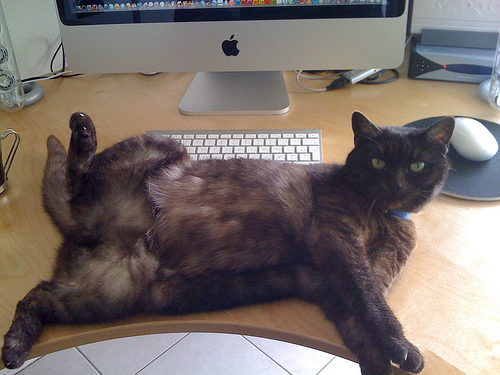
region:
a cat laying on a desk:
[4, 93, 480, 373]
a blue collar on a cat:
[333, 167, 418, 225]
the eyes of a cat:
[367, 155, 434, 172]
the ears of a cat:
[347, 109, 457, 148]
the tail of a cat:
[39, 130, 80, 231]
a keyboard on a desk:
[146, 122, 337, 169]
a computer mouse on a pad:
[447, 111, 499, 167]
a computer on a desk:
[50, 3, 432, 110]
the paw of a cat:
[60, 110, 102, 151]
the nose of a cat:
[383, 172, 405, 194]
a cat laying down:
[34, 93, 472, 331]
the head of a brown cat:
[345, 108, 446, 215]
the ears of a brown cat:
[325, 99, 466, 146]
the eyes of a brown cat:
[351, 141, 439, 181]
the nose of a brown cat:
[390, 168, 415, 193]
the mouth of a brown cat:
[380, 186, 412, 213]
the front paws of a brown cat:
[328, 241, 432, 373]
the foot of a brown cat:
[60, 115, 131, 192]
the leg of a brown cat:
[11, 265, 135, 332]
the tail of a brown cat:
[31, 122, 89, 223]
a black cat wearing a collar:
[38, 115, 441, 333]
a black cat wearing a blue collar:
[30, 112, 460, 348]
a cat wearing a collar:
[46, 105, 468, 371]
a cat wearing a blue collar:
[43, 114, 479, 345]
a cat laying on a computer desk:
[28, 105, 486, 336]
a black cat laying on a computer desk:
[23, 118, 488, 358]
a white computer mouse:
[370, 74, 495, 209]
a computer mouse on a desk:
[358, 85, 498, 189]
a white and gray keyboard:
[113, 103, 365, 211]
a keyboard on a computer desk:
[128, 110, 386, 229]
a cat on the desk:
[38, 86, 472, 339]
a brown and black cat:
[62, 114, 429, 357]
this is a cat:
[7, 71, 449, 373]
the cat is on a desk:
[6, 66, 461, 372]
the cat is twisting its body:
[10, 87, 476, 372]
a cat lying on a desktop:
[3, 91, 448, 373]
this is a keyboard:
[140, 118, 325, 178]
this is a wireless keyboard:
[132, 123, 327, 184]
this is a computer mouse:
[442, 93, 498, 171]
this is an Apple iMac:
[49, 3, 420, 110]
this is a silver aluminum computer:
[54, 1, 415, 118]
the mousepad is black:
[387, 104, 497, 209]